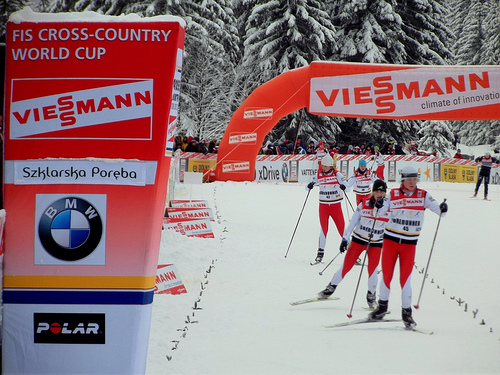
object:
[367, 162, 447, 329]
skier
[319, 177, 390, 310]
skier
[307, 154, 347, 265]
skier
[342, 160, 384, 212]
skier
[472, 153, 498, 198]
skier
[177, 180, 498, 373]
path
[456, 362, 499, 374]
snow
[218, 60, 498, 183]
sign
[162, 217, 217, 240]
advertisement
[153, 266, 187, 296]
advertisement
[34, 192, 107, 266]
advertisement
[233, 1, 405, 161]
tree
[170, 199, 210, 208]
sign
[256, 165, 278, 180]
lettering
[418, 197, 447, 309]
ski pole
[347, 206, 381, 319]
ski pole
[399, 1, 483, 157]
tree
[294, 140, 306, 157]
person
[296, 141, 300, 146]
head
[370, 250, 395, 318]
leg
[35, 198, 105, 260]
logo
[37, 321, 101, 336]
word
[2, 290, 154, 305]
stripe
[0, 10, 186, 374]
sign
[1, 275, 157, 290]
stripe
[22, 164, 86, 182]
word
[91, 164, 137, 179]
word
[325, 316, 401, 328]
ski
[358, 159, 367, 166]
cap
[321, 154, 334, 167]
cap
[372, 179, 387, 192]
cap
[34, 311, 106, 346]
polar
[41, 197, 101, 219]
bmw